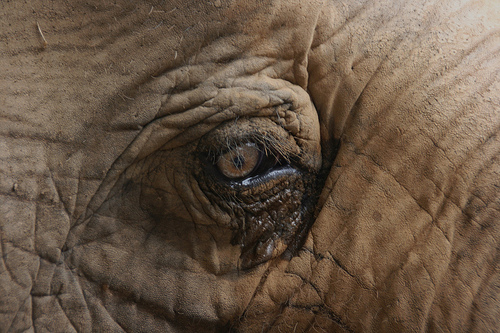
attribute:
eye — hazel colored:
[211, 140, 261, 180]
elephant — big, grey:
[1, 1, 484, 331]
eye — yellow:
[175, 136, 266, 186]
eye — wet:
[191, 95, 330, 225]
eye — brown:
[204, 130, 307, 200]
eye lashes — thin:
[220, 136, 298, 162]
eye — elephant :
[206, 131, 295, 197]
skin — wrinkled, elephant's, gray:
[4, 5, 497, 331]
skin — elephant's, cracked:
[86, 211, 385, 331]